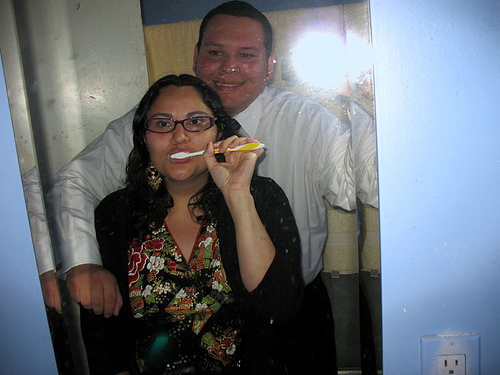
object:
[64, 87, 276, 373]
lady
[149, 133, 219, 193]
mouth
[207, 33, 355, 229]
man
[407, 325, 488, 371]
plate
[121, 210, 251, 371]
blouse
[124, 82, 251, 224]
hair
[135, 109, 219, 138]
glasses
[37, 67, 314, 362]
woman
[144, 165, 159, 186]
earrings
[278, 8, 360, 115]
camera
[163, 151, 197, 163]
teeth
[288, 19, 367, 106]
flash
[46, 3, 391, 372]
he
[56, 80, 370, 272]
shirt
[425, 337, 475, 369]
outlet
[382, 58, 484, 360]
wall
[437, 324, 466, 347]
paint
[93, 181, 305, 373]
dress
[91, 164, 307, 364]
jacket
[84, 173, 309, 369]
sweater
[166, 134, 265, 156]
toothbrush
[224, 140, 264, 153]
stripe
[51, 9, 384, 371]
man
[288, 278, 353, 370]
pants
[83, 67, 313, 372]
girl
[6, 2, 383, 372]
mirror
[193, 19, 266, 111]
face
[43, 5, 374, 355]
picture